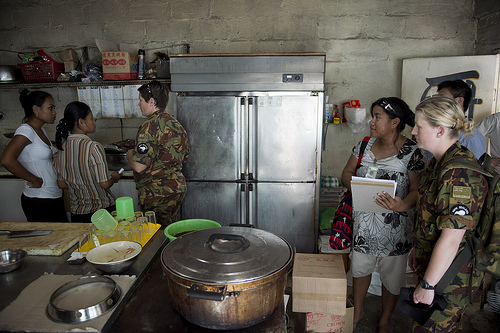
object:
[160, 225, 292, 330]
pot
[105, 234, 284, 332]
stove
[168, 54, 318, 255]
fridge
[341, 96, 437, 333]
woman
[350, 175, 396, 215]
note pad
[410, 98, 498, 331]
soldier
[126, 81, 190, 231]
soldier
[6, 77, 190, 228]
cooking lessons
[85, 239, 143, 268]
dishes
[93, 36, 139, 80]
box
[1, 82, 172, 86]
shelf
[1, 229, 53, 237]
knife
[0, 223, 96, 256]
cutting board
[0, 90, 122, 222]
girls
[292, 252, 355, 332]
boxes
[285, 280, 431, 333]
floor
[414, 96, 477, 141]
blonde hair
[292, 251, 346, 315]
box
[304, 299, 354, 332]
box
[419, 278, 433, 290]
wrist watch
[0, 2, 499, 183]
cement wall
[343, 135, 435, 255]
black and white top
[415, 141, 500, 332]
camoflauge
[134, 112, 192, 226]
camoflauge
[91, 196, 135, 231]
containers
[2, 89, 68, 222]
woman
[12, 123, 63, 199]
white t-shirt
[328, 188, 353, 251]
purse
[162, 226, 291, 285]
lid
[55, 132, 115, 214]
shirt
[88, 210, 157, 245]
glasses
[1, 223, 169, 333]
counter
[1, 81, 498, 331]
people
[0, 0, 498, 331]
kitchen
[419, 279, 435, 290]
wrist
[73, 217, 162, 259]
tray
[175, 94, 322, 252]
double door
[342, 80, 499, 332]
people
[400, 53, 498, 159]
door